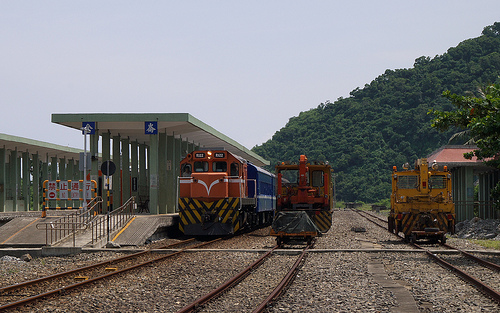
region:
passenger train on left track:
[172, 144, 293, 241]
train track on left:
[2, 233, 223, 308]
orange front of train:
[169, 140, 251, 207]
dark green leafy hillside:
[242, 20, 498, 215]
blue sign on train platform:
[139, 118, 161, 139]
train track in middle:
[172, 237, 324, 312]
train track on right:
[345, 203, 499, 311]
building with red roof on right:
[420, 138, 499, 238]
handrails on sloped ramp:
[36, 195, 141, 252]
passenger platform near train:
[46, 107, 275, 224]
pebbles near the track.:
[306, 282, 321, 305]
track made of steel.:
[269, 278, 284, 297]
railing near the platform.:
[95, 218, 105, 237]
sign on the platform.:
[142, 120, 157, 135]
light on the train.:
[205, 145, 214, 161]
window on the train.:
[210, 161, 224, 170]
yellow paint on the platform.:
[11, 216, 31, 244]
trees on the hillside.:
[344, 110, 367, 132]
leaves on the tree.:
[477, 107, 489, 129]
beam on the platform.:
[146, 150, 160, 201]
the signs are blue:
[73, 109, 174, 150]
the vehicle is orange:
[387, 157, 464, 251]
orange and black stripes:
[393, 207, 455, 239]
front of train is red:
[169, 137, 246, 234]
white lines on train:
[179, 174, 221, 197]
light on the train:
[199, 145, 217, 159]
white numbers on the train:
[186, 146, 228, 163]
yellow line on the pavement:
[104, 214, 144, 250]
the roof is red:
[431, 139, 489, 169]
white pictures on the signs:
[76, 120, 164, 138]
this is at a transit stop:
[22, 37, 482, 308]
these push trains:
[222, 149, 492, 306]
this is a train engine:
[154, 146, 271, 249]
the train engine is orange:
[180, 144, 272, 246]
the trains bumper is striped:
[180, 192, 240, 234]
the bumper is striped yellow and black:
[168, 190, 325, 312]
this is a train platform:
[47, 112, 185, 269]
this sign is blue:
[70, 113, 104, 137]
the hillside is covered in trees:
[311, 81, 461, 167]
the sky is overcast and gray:
[50, 9, 280, 85]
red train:
[162, 134, 260, 244]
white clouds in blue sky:
[5, 17, 81, 72]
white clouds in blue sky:
[216, 23, 258, 67]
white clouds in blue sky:
[203, 46, 247, 88]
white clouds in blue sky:
[276, 42, 320, 68]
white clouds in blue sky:
[37, 5, 113, 65]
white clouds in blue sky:
[149, 28, 206, 74]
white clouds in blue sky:
[217, 55, 268, 87]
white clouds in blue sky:
[187, 25, 245, 96]